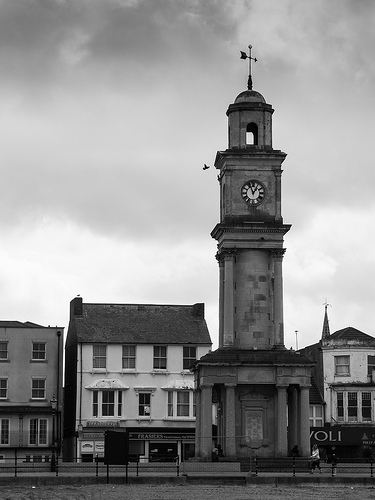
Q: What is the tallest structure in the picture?
A: Clock Tower.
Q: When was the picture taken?
A: Daytime.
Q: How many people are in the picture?
A: One.